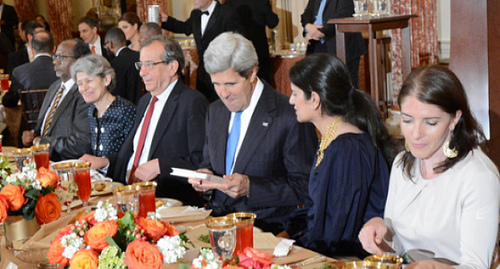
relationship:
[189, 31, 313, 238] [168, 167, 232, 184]
man holding book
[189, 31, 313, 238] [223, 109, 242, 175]
man has tie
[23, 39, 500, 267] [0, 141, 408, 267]
people at dinner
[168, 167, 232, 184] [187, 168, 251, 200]
book in hands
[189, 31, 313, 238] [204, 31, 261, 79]
man has hair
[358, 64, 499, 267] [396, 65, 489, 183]
woman has hair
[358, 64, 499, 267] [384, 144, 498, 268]
woman wearing shirt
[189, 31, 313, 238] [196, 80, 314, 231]
man wearing jacket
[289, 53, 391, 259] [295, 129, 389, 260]
woman wearing dress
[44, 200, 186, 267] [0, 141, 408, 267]
flower at dinner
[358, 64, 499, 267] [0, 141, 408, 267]
woman at dinner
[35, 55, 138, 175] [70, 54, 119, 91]
woman has hair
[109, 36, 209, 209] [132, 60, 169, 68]
man has glasses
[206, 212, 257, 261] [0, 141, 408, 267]
drinks at dinner